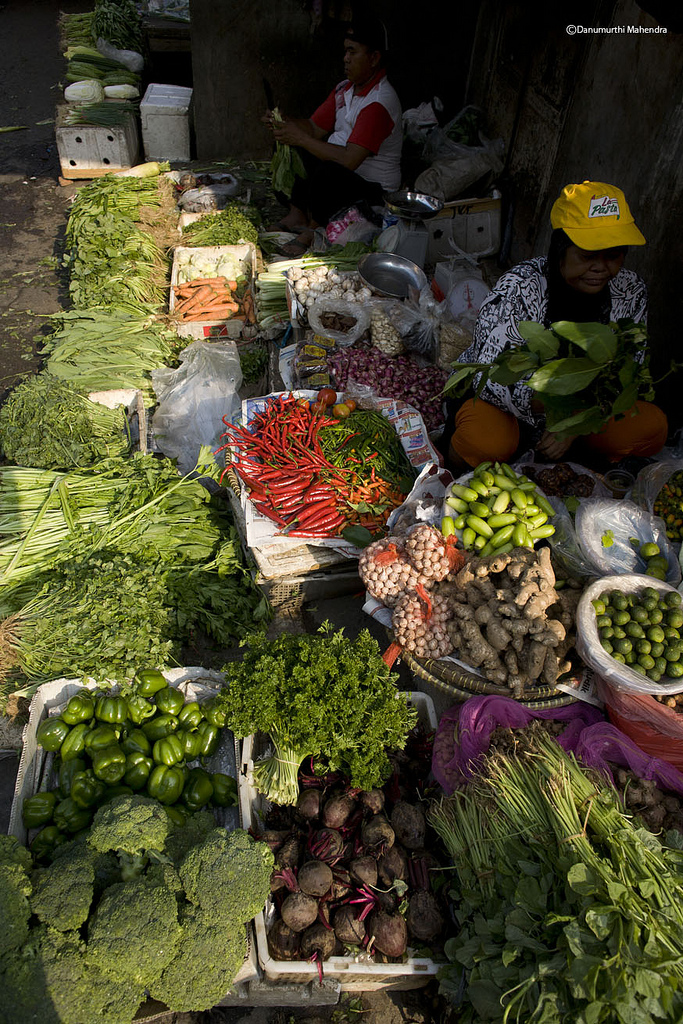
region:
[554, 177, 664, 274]
Person wearing yellow hat.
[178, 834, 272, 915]
Green head of broccoli.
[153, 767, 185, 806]
Green pepper in tub.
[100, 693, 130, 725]
Green pepper in tub.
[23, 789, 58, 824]
Green pepper in tub.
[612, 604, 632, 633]
Green lime in basket.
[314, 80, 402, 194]
Person wearing red and white shirt.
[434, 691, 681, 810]
a purple scarf among the vegetables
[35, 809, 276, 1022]
a group of broccoli stalks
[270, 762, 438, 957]
a bin of red beets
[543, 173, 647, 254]
a yellow hat on her head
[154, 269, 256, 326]
a bunch of carrots together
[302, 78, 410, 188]
a red and white shirt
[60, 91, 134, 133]
small bunches of green onions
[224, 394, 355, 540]
long skinny red peppers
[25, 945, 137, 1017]
vegetables in a box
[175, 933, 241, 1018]
vegetables in a box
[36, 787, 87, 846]
vegetables in a box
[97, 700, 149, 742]
vegetable in a box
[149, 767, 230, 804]
vegetables in a box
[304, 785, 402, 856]
vegetables in a box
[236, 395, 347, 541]
fresh food is in a basket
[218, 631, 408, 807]
fresh food is in a basket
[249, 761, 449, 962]
fresh food is in a basket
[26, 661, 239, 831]
fresh food is in a basket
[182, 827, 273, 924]
fresh food is in a basket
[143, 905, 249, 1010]
fresh food is in a basket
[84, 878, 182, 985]
fresh food is in a basket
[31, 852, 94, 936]
fresh food is in a basket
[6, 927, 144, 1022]
fresh food is in a basket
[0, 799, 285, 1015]
The bunch of broccolli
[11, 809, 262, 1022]
A bunch of broccoli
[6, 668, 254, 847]
The bunch of green peppers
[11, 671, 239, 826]
A bunch of green peppers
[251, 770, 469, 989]
The bunch of red beets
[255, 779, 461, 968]
A bunch of red beets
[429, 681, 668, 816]
The pink scarf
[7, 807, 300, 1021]
A set of broccoli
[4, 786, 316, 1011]
The set of broccoli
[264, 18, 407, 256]
woman sits among her produce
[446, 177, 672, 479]
woman working behind the stand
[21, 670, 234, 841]
green peppers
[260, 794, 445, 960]
beets are in a container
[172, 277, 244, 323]
just a few orange carrots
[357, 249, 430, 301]
pan to weigh produce in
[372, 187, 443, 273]
scale to weigh food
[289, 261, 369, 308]
cloves of garlic in back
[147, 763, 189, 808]
green pepper by broccoli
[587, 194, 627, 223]
white sign with green writing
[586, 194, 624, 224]
white sign on yellow hat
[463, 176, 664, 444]
woman wearing yellow hat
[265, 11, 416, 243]
man wearing red and white shirt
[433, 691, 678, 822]
purple cloth laying on table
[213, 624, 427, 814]
bunch of lettuce on beets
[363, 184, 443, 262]
scales sitting by the man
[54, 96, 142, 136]
green onions laying on box